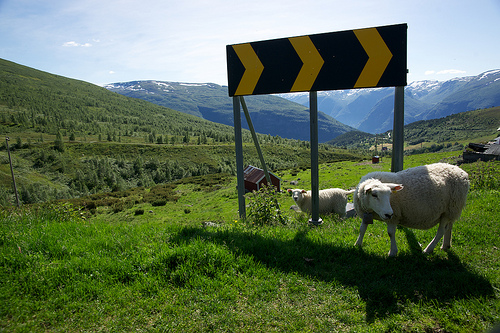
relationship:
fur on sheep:
[412, 180, 442, 215] [325, 152, 485, 283]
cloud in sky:
[426, 62, 461, 84] [403, 19, 498, 129]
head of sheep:
[354, 175, 419, 245] [343, 167, 493, 291]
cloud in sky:
[23, 34, 460, 84] [33, 2, 167, 97]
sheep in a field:
[343, 147, 469, 257] [7, 126, 378, 327]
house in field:
[241, 161, 284, 196] [137, 147, 463, 329]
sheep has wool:
[343, 147, 469, 257] [393, 160, 470, 225]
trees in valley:
[75, 158, 175, 193] [33, 127, 286, 204]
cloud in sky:
[23, 34, 460, 84] [9, 7, 485, 79]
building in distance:
[242, 164, 280, 193] [113, 92, 339, 187]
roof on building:
[241, 160, 279, 184] [245, 160, 280, 195]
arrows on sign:
[349, 28, 393, 88] [223, 20, 411, 100]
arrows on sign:
[288, 35, 325, 89] [223, 20, 411, 100]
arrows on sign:
[232, 40, 262, 96] [223, 20, 411, 100]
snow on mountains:
[106, 75, 207, 92] [99, 75, 355, 149]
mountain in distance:
[12, 60, 477, 173] [103, 65, 483, 134]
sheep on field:
[343, 147, 469, 257] [35, 177, 467, 310]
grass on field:
[10, 186, 472, 316] [20, 167, 485, 326]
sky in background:
[1, 0, 499, 87] [59, 10, 477, 97]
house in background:
[241, 161, 284, 196] [55, 47, 452, 189]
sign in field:
[224, 21, 410, 98] [1, 56, 499, 330]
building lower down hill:
[242, 164, 280, 193] [1, 59, 499, 331]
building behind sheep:
[457, 136, 498, 166] [343, 147, 469, 257]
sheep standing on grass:
[343, 147, 469, 257] [1, 59, 499, 331]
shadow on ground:
[171, 222, 496, 322] [0, 133, 499, 330]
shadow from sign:
[171, 222, 496, 322] [227, 21, 409, 223]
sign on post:
[224, 21, 410, 98] [234, 88, 404, 224]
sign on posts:
[224, 10, 412, 240] [219, 96, 423, 270]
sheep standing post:
[343, 147, 469, 257] [387, 91, 416, 248]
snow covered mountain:
[146, 70, 170, 82] [157, 60, 478, 119]